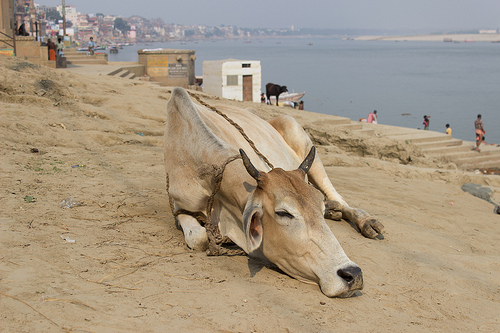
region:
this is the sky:
[337, 1, 449, 24]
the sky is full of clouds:
[323, 2, 413, 19]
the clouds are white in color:
[302, 5, 369, 20]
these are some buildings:
[58, 7, 230, 39]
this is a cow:
[143, 80, 403, 295]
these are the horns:
[235, 142, 320, 173]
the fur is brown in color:
[273, 174, 290, 189]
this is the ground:
[25, 155, 135, 288]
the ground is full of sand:
[41, 206, 131, 286]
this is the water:
[328, 52, 471, 88]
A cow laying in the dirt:
[136, 77, 424, 304]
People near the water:
[352, 96, 498, 154]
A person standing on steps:
[445, 92, 499, 166]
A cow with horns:
[151, 36, 401, 311]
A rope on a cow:
[176, 77, 286, 276]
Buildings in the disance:
[26, 5, 300, 53]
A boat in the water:
[266, 88, 314, 108]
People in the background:
[11, 14, 110, 69]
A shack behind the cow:
[191, 50, 276, 115]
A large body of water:
[114, 25, 497, 134]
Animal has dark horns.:
[232, 145, 357, 170]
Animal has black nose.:
[327, 251, 362, 297]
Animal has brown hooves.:
[354, 215, 396, 257]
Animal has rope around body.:
[187, 147, 263, 282]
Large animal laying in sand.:
[161, 87, 357, 312]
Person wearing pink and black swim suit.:
[466, 124, 494, 159]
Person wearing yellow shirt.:
[436, 121, 472, 166]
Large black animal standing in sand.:
[261, 66, 299, 128]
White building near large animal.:
[200, 49, 286, 121]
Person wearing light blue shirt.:
[79, 30, 102, 50]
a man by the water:
[468, 112, 490, 156]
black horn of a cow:
[233, 144, 268, 184]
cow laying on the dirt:
[157, 80, 392, 306]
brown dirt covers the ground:
[396, 206, 465, 310]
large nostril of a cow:
[335, 266, 360, 286]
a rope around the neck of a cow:
[198, 150, 271, 259]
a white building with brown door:
[198, 53, 262, 108]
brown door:
[240, 72, 256, 102]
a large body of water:
[325, 45, 492, 105]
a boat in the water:
[261, 91, 308, 101]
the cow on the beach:
[134, 36, 401, 313]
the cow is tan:
[122, 42, 395, 319]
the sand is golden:
[59, 176, 132, 275]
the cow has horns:
[134, 42, 421, 314]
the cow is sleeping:
[147, 31, 413, 318]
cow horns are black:
[136, 53, 428, 327]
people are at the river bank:
[356, 65, 497, 162]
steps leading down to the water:
[42, 19, 497, 241]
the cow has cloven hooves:
[334, 199, 399, 249]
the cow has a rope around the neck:
[156, 59, 393, 306]